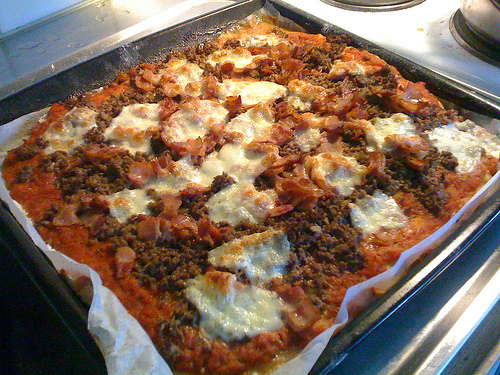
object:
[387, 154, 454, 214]
topping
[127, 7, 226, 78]
plate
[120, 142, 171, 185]
topping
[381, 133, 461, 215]
meat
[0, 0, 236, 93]
top surface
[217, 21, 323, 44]
sauce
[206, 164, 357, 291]
topping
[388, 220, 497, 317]
blue backdrop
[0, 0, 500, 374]
dish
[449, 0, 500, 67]
structure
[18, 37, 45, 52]
liquid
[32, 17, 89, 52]
surface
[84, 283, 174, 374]
liner paper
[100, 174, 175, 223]
cheese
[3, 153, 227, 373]
sauce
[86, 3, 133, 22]
patch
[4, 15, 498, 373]
food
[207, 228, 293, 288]
cheese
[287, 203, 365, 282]
meat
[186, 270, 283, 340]
cheese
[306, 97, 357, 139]
topping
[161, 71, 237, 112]
topping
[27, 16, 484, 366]
pasta mix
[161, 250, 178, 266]
topping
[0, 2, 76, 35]
backdrop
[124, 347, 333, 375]
edges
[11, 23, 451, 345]
mix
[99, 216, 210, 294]
meat